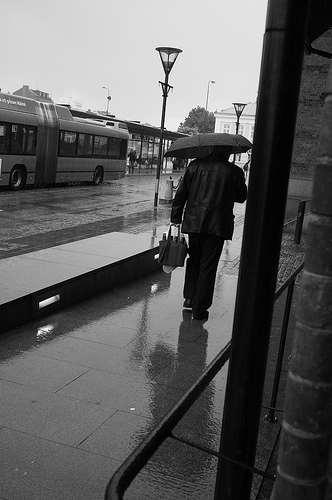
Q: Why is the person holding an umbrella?
A: Raining.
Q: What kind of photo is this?
A: Black and white.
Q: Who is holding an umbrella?
A: Person.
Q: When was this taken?
A: Daytime.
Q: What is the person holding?
A: Umbrella.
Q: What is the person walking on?
A: Sidewalk.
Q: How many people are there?
A: 1.